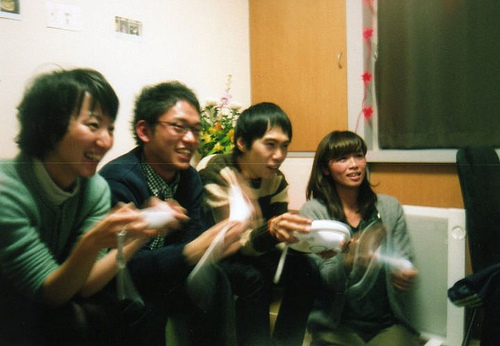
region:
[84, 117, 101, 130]
the eye of a woman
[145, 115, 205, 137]
a pair of glasses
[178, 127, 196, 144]
the nose of a man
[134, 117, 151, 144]
the ear of a man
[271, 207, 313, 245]
the hand of a man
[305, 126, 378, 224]
the hair of a woman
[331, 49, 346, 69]
a metal door handle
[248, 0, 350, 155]
a brown wooden door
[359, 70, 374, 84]
a red star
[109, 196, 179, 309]
a white remote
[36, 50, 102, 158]
Person has dark hair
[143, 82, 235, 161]
Person has dark hair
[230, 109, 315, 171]
Person has dark hair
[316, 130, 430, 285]
Woman has long dark hair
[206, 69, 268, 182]
Bouquet of flowers behind man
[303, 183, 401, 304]
Woman wearing gray sweater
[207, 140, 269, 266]
Person wearing striped sweater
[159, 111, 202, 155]
Glasses on man's face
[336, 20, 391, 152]
Red star shaped lights hanging on window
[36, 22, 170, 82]
Back wall is white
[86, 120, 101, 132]
the eye of the woman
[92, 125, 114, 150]
the nose of the woman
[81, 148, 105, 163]
the mouth of the woman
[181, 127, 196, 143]
the nose of the man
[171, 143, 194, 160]
the mouth of the man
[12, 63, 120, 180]
the head of a woman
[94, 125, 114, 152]
the nose of a woman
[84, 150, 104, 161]
the teeth of a woman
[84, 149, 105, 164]
the mouth of a woman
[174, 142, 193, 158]
the mouth of a man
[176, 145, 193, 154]
the teeth of a man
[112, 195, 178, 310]
a white controller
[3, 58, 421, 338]
a group of friends playing games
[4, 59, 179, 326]
a woman holding a Wii remote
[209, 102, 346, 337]
a man holding a Wii steering wheel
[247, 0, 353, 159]
a panel door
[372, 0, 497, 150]
green curtains over a window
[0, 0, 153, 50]
picture hung on the wall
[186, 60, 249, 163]
a flowered, potted plant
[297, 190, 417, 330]
a woman in a gray sweater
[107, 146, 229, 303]
a man in a blue sweater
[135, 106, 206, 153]
a man wearing glasses